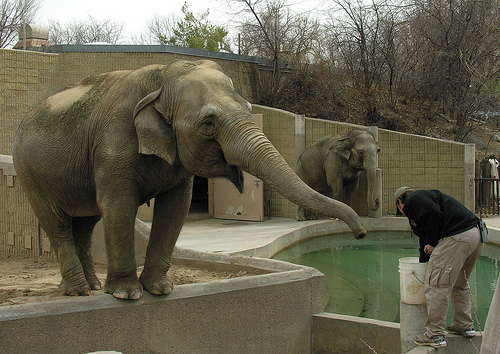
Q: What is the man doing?
A: Reaching for something in bucket.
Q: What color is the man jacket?
A: Black.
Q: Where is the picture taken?
A: A zoo.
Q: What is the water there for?
A: The elephants to play in.